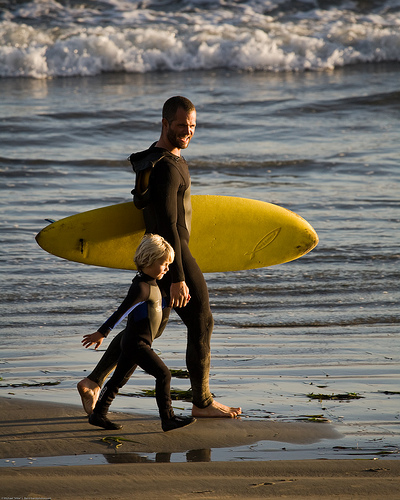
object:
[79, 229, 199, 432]
boy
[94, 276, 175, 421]
wet suit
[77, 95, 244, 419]
man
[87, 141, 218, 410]
wet suit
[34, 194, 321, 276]
board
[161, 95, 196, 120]
hair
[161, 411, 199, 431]
shoe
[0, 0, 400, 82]
wave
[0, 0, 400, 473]
water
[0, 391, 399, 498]
sand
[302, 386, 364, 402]
seaweed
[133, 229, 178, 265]
hair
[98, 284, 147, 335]
arm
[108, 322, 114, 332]
stripe